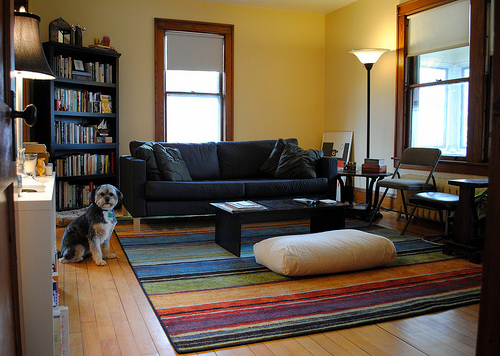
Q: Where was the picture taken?
A: It was taken at the living room.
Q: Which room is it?
A: It is a living room.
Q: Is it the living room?
A: Yes, it is the living room.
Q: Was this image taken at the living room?
A: Yes, it was taken in the living room.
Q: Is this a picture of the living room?
A: Yes, it is showing the living room.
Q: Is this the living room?
A: Yes, it is the living room.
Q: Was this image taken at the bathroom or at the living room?
A: It was taken at the living room.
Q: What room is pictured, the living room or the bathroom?
A: It is the living room.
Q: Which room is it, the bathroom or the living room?
A: It is the living room.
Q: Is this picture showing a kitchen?
A: No, the picture is showing a living room.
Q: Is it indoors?
A: Yes, it is indoors.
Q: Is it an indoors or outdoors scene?
A: It is indoors.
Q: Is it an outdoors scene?
A: No, it is indoors.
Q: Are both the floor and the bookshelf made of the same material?
A: Yes, both the floor and the bookshelf are made of wood.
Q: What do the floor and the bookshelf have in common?
A: The material, both the floor and the bookshelf are wooden.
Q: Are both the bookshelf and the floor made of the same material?
A: Yes, both the bookshelf and the floor are made of wood.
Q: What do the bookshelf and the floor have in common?
A: The material, both the bookshelf and the floor are wooden.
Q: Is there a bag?
A: No, there are no bags.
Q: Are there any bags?
A: No, there are no bags.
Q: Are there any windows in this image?
A: Yes, there is a window.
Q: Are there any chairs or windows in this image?
A: Yes, there is a window.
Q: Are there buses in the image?
A: No, there are no buses.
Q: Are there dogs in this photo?
A: Yes, there is a dog.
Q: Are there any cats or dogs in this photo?
A: Yes, there is a dog.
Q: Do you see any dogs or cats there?
A: Yes, there is a dog.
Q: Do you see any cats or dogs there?
A: Yes, there is a dog.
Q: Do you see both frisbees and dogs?
A: No, there is a dog but no frisbees.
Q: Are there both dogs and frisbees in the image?
A: No, there is a dog but no frisbees.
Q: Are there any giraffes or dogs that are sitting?
A: Yes, the dog is sitting.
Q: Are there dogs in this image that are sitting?
A: Yes, there is a dog that is sitting.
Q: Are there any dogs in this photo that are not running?
A: Yes, there is a dog that is sitting.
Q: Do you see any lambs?
A: No, there are no lambs.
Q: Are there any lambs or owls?
A: No, there are no lambs or owls.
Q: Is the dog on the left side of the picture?
A: Yes, the dog is on the left of the image.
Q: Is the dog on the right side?
A: No, the dog is on the left of the image.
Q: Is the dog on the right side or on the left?
A: The dog is on the left of the image.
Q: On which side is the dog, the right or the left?
A: The dog is on the left of the image.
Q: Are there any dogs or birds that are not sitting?
A: No, there is a dog but it is sitting.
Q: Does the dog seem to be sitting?
A: Yes, the dog is sitting.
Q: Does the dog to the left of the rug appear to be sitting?
A: Yes, the dog is sitting.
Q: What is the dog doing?
A: The dog is sitting.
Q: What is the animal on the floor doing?
A: The dog is sitting.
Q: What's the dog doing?
A: The dog is sitting.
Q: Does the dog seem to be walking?
A: No, the dog is sitting.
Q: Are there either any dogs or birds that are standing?
A: No, there is a dog but it is sitting.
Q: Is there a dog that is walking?
A: No, there is a dog but it is sitting.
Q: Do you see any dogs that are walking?
A: No, there is a dog but it is sitting.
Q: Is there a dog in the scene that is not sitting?
A: No, there is a dog but it is sitting.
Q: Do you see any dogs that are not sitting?
A: No, there is a dog but it is sitting.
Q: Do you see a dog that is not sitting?
A: No, there is a dog but it is sitting.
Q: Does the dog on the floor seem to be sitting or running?
A: The dog is sitting.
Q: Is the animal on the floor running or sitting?
A: The dog is sitting.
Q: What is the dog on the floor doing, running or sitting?
A: The dog is sitting.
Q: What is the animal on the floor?
A: The animal is a dog.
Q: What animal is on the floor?
A: The animal is a dog.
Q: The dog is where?
A: The dog is on the floor.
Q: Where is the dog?
A: The dog is on the floor.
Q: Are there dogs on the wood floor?
A: Yes, there is a dog on the floor.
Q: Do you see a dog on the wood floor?
A: Yes, there is a dog on the floor.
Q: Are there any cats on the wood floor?
A: No, there is a dog on the floor.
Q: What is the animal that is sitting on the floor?
A: The animal is a dog.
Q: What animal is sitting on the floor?
A: The animal is a dog.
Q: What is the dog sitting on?
A: The dog is sitting on the floor.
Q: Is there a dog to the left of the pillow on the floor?
A: Yes, there is a dog to the left of the pillow.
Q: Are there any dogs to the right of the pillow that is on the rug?
A: No, the dog is to the left of the pillow.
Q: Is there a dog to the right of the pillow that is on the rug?
A: No, the dog is to the left of the pillow.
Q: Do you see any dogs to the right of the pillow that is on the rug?
A: No, the dog is to the left of the pillow.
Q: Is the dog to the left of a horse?
A: No, the dog is to the left of the pillow.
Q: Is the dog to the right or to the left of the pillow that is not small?
A: The dog is to the left of the pillow.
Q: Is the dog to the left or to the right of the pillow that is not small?
A: The dog is to the left of the pillow.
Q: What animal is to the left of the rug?
A: The animal is a dog.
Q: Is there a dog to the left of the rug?
A: Yes, there is a dog to the left of the rug.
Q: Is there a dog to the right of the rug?
A: No, the dog is to the left of the rug.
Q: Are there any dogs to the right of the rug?
A: No, the dog is to the left of the rug.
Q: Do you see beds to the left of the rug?
A: No, there is a dog to the left of the rug.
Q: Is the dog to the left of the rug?
A: Yes, the dog is to the left of the rug.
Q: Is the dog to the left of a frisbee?
A: No, the dog is to the left of the rug.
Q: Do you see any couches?
A: Yes, there is a couch.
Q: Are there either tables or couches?
A: Yes, there is a couch.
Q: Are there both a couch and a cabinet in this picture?
A: No, there is a couch but no cabinets.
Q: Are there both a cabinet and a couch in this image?
A: No, there is a couch but no cabinets.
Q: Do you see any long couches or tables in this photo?
A: Yes, there is a long couch.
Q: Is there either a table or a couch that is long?
A: Yes, the couch is long.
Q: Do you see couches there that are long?
A: Yes, there is a long couch.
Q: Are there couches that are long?
A: Yes, there is a couch that is long.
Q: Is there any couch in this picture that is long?
A: Yes, there is a couch that is long.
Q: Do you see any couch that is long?
A: Yes, there is a couch that is long.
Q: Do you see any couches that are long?
A: Yes, there is a couch that is long.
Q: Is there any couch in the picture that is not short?
A: Yes, there is a long couch.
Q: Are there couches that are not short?
A: Yes, there is a long couch.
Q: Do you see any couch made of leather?
A: Yes, there is a couch that is made of leather.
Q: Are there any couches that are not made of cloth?
A: Yes, there is a couch that is made of leather.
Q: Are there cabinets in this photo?
A: No, there are no cabinets.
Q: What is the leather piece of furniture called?
A: The piece of furniture is a couch.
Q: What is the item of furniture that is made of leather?
A: The piece of furniture is a couch.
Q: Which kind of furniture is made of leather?
A: The furniture is a couch.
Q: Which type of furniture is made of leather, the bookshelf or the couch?
A: The couch is made of leather.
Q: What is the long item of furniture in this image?
A: The piece of furniture is a couch.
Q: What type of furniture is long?
A: The furniture is a couch.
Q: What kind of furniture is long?
A: The furniture is a couch.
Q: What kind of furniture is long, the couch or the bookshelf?
A: The couch is long.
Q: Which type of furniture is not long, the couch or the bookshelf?
A: The bookshelf is not long.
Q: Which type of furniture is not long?
A: The furniture is a bookshelf.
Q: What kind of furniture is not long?
A: The furniture is a bookshelf.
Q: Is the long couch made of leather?
A: Yes, the couch is made of leather.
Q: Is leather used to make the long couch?
A: Yes, the couch is made of leather.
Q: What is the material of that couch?
A: The couch is made of leather.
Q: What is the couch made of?
A: The couch is made of leather.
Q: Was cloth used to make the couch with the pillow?
A: No, the couch is made of leather.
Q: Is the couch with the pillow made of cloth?
A: No, the couch is made of leather.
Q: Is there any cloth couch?
A: No, there is a couch but it is made of leather.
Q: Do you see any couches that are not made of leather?
A: No, there is a couch but it is made of leather.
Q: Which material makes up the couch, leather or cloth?
A: The couch is made of leather.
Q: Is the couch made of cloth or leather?
A: The couch is made of leather.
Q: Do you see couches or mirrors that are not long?
A: No, there is a couch but it is long.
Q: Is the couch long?
A: Yes, the couch is long.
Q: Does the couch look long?
A: Yes, the couch is long.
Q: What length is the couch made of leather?
A: The couch is long.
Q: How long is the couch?
A: The couch is long.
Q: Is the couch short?
A: No, the couch is long.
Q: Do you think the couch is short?
A: No, the couch is long.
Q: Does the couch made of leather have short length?
A: No, the couch is long.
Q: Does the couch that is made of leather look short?
A: No, the couch is long.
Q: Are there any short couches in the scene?
A: No, there is a couch but it is long.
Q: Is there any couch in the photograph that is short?
A: No, there is a couch but it is long.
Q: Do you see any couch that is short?
A: No, there is a couch but it is long.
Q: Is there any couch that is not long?
A: No, there is a couch but it is long.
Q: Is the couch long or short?
A: The couch is long.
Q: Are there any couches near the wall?
A: Yes, there is a couch near the wall.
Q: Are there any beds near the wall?
A: No, there is a couch near the wall.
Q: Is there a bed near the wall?
A: No, there is a couch near the wall.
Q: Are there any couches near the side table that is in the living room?
A: Yes, there is a couch near the side table.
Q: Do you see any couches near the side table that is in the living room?
A: Yes, there is a couch near the side table.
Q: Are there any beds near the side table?
A: No, there is a couch near the side table.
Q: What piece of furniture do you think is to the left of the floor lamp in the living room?
A: The piece of furniture is a couch.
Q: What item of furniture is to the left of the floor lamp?
A: The piece of furniture is a couch.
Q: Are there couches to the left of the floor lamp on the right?
A: Yes, there is a couch to the left of the floor lamp.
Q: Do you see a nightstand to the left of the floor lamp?
A: No, there is a couch to the left of the floor lamp.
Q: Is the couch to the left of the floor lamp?
A: Yes, the couch is to the left of the floor lamp.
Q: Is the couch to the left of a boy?
A: No, the couch is to the left of the floor lamp.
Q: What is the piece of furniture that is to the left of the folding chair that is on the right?
A: The piece of furniture is a couch.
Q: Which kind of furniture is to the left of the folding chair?
A: The piece of furniture is a couch.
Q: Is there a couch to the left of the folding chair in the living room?
A: Yes, there is a couch to the left of the folding chair.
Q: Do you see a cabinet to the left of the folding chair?
A: No, there is a couch to the left of the folding chair.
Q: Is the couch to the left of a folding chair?
A: Yes, the couch is to the left of a folding chair.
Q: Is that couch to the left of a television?
A: No, the couch is to the left of a folding chair.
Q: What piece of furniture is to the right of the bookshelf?
A: The piece of furniture is a couch.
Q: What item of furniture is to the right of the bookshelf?
A: The piece of furniture is a couch.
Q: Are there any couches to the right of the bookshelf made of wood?
A: Yes, there is a couch to the right of the bookshelf.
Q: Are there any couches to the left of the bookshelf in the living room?
A: No, the couch is to the right of the bookshelf.